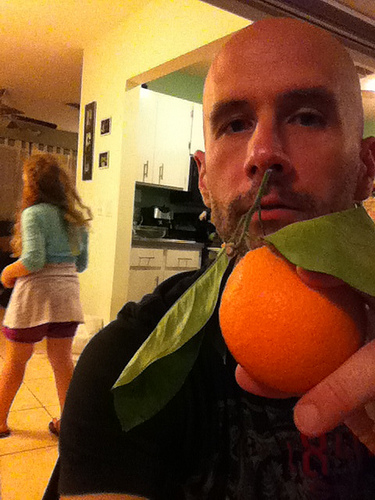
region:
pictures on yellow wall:
[70, 103, 127, 175]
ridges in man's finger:
[321, 376, 348, 407]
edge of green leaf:
[113, 352, 175, 400]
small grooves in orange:
[253, 306, 303, 366]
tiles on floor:
[22, 437, 54, 471]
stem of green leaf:
[228, 161, 297, 259]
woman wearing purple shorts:
[4, 307, 98, 353]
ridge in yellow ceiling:
[25, 13, 155, 70]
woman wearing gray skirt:
[9, 269, 111, 354]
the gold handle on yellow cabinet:
[133, 149, 185, 197]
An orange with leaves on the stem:
[122, 226, 373, 427]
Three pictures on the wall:
[79, 91, 123, 201]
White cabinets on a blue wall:
[138, 88, 195, 230]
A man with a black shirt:
[212, 0, 371, 495]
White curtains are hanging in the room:
[0, 100, 75, 180]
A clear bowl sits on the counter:
[132, 213, 172, 242]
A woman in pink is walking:
[9, 152, 77, 440]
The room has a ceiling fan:
[3, 86, 64, 142]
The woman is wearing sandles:
[0, 395, 77, 440]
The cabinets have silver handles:
[132, 249, 204, 264]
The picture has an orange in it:
[5, 119, 372, 491]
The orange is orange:
[230, 244, 362, 414]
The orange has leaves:
[109, 155, 370, 432]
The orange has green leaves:
[73, 190, 372, 370]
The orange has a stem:
[225, 157, 301, 271]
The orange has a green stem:
[223, 136, 279, 282]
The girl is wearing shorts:
[2, 291, 93, 340]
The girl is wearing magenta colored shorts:
[2, 301, 92, 346]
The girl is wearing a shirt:
[12, 202, 98, 286]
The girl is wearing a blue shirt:
[8, 192, 101, 284]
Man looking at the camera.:
[170, 1, 374, 244]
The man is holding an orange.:
[225, 248, 353, 408]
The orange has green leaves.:
[260, 199, 374, 286]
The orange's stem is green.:
[219, 160, 280, 241]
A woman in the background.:
[5, 146, 80, 421]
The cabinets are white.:
[142, 102, 190, 176]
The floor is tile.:
[13, 436, 59, 499]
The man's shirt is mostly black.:
[77, 377, 374, 489]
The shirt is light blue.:
[15, 204, 92, 261]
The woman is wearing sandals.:
[43, 410, 84, 451]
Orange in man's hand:
[215, 232, 367, 424]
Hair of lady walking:
[26, 150, 91, 240]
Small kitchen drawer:
[128, 243, 165, 269]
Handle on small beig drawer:
[132, 250, 155, 261]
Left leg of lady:
[150, 95, 188, 193]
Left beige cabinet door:
[152, 83, 192, 192]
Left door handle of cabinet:
[152, 157, 162, 179]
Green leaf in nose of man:
[115, 165, 312, 405]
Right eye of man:
[202, 84, 266, 138]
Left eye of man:
[276, 96, 351, 141]